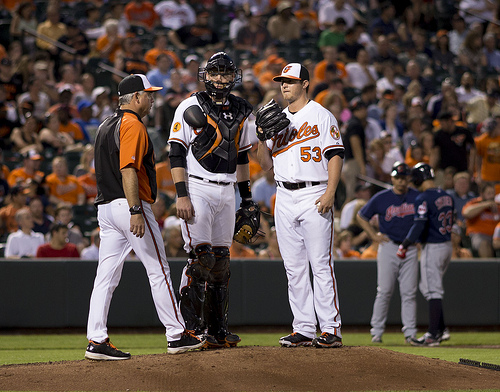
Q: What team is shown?
A: Orioles.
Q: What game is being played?
A: Baseball.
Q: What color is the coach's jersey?
A: Orange.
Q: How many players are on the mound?
A: 3.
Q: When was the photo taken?
A: Game.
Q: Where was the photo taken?
A: Stadium.